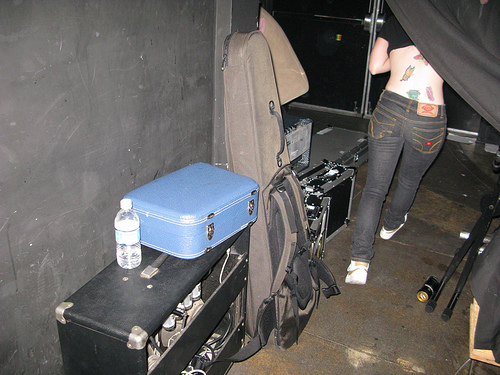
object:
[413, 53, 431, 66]
tattoo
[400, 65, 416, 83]
tattoo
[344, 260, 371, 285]
shoe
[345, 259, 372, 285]
foot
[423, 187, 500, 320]
stand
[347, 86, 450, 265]
pants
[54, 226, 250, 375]
black case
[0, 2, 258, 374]
wall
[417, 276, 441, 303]
can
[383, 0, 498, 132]
curtain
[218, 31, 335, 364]
guitar case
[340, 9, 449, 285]
person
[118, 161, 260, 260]
blue luggage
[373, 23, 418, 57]
shirt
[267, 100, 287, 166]
handle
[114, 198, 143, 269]
bottle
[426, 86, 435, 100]
tattoo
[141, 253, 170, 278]
handle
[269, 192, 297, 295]
shoulder strap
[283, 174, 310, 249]
shoulder strap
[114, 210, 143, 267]
water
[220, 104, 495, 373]
floor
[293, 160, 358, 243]
case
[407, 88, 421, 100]
tattoo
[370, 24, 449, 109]
back